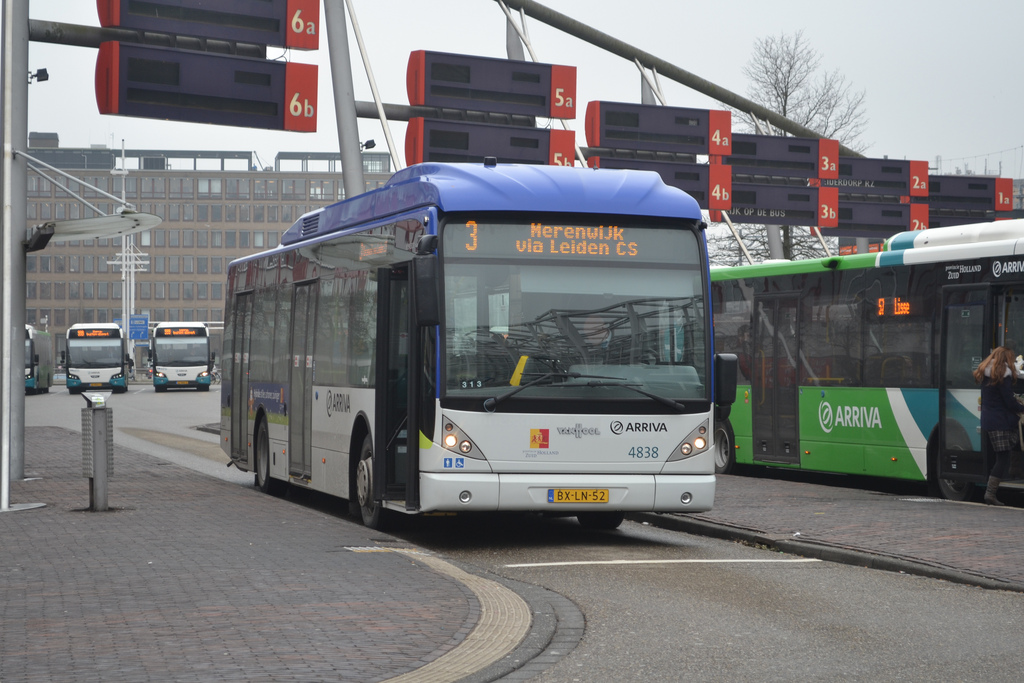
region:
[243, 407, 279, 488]
the back tire of the bus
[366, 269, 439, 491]
it is the door of the bus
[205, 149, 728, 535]
a blue and white city bus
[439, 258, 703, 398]
it is the windshield of the bus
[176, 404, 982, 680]
the road is grey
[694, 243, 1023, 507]
a bus that is green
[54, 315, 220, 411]
buses are in the background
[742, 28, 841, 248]
a tree with no leaves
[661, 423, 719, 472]
the front light of the bus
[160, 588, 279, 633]
the sidewalk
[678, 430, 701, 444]
the headlight on the bus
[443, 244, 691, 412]
windshield on the bus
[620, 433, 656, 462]
numbers on the bus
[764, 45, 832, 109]
tree branches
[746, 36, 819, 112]
branches on the tree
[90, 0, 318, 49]
sign at the bus depot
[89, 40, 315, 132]
sign at the bus depot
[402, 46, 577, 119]
sign at the bus depot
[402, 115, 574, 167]
sign at the bus depot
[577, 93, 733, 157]
sign at the bus depot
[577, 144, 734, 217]
sign at the bus depot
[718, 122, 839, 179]
sign at the bus depot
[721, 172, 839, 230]
sign at the bus depot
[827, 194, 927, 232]
sign at the bus depot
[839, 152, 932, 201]
sign at the bus depot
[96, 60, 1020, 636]
this is a metro bus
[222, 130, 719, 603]
the bus is blue and white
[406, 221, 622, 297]
the bus has writing on it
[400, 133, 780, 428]
the writing is orange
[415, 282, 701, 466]
this is a windshield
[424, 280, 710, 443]
the windshield is reflective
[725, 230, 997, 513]
this bus is green and white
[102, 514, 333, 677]
the sidewalk is brick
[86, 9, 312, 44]
sign on the pole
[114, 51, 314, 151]
sign on the pole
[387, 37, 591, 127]
sign on the pole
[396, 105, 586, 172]
sign on the pole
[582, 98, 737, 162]
sign on the pole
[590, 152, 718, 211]
sign on the pole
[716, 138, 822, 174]
sign on the pole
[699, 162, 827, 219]
sign on the pole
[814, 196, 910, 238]
sign on the pole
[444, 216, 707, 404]
glass is clear and clean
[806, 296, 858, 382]
glass is clear and clean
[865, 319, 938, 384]
glass is clear and clean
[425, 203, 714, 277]
digital display on bus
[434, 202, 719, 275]
digital display on bus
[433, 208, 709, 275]
digital display on bus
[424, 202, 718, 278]
digital display on bus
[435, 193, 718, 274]
digital display on bus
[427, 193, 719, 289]
digital display on bus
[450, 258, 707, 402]
glass is clear and clean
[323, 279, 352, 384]
glass is clear and clean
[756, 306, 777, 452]
glass is clear and clean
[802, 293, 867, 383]
glass is clear and clean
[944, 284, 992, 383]
glass is clear and clean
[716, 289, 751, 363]
glass is clear and clean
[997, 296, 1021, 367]
glass is clear and clean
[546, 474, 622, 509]
license plate on the bus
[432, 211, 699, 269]
electric sign on the bus